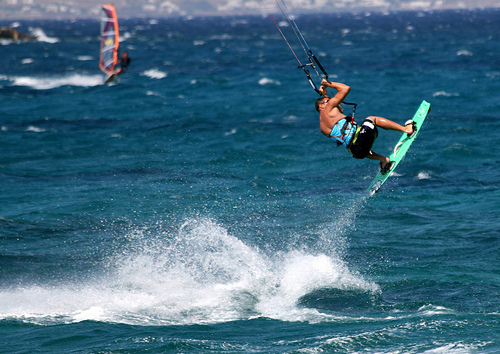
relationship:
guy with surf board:
[314, 77, 414, 174] [362, 100, 430, 200]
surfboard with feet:
[361, 98, 431, 201] [381, 118, 408, 165]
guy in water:
[314, 77, 415, 169] [2, 12, 498, 345]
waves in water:
[0, 211, 389, 328] [2, 12, 498, 345]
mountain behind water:
[3, 16, 45, 57] [2, 12, 498, 345]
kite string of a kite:
[261, 0, 306, 72] [266, 1, 299, 11]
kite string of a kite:
[257, 0, 309, 74] [266, 1, 299, 11]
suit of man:
[325, 116, 382, 152] [316, 80, 413, 176]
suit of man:
[345, 118, 379, 159] [308, 79, 415, 175]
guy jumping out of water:
[314, 77, 415, 169] [2, 12, 498, 345]